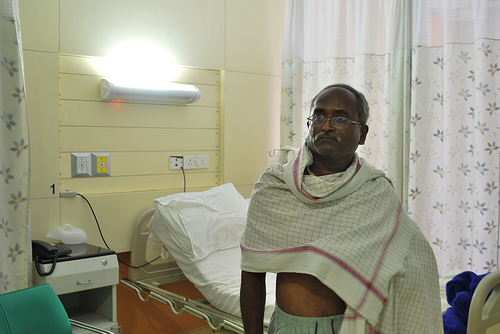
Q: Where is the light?
A: On the wall.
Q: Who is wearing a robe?
A: The man.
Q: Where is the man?
A: In front of the bed.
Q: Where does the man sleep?
A: In the bed.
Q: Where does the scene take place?
A: In a hospital room.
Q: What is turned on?
A: A light on the wall.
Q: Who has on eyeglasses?
A: The man.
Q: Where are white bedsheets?
A: On the bed.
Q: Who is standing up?
A: The man.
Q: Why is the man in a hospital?
A: To be treated.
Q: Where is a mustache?
A: On man's face.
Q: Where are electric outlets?
A: On the wall.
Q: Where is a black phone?
A: On small table.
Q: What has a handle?
A: A drawer.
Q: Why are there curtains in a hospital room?
A: Privacy.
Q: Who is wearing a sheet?
A: The male patient.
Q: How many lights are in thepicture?
A: One.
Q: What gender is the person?
A: Male.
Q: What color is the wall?
A: Yellow.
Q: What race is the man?
A: Indian.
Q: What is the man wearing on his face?
A: Glasses.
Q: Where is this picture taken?
A: Hospital.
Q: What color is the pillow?
A: White.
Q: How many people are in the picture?
A: One.